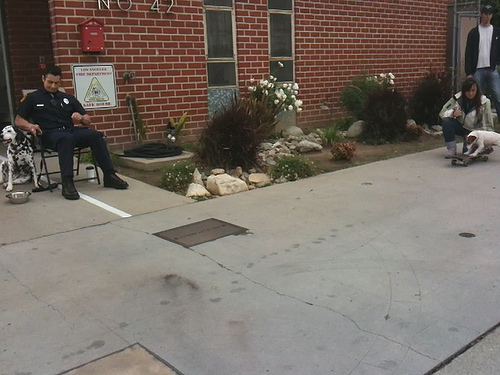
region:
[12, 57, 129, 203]
a man in a uniform sits in a chair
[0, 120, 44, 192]
a dalmation is sitting on the floor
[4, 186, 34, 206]
metal dog water bowl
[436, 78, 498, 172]
a girl with a dog on a skateboard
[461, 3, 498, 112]
a man stands and stares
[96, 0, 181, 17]
no 42 on a red brick wall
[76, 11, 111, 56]
a red mail box on a wall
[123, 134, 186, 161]
a black hose is coiled up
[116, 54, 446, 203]
plants and rocks in a small front yard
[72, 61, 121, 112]
a sign on a red brick wall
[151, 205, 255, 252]
metal grate on the sidewalk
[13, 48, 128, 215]
fireman in a uniform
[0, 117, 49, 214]
white dog with black spots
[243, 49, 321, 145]
white flowers in landscaping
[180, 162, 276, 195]
rocks in the landscaping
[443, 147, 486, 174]
paws on a skateboard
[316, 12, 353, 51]
red bricks on the wall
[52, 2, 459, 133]
building made of brick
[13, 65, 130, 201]
man is sitting in chair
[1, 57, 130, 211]
dalmation dog beside man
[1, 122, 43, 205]
silver bowl in front of dog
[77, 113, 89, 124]
man is wearing a watch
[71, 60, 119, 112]
white sign on building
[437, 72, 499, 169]
woman is petting dog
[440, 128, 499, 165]
dog is trying to skateboard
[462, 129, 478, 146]
brown spot on dog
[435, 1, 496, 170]
man is standing behind woman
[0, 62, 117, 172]
man sitting in chair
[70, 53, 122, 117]
white sign on wall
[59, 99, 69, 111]
silver badge on shirt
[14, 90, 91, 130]
black shirt on man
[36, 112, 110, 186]
black pants on man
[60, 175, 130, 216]
black shoes on feet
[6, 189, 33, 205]
silver dog bowl on ground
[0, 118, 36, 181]
white and black dog sitting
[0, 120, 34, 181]
white and black dalmation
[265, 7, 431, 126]
large red brick wall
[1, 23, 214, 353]
cop by sidewalk with dog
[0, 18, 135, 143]
cop by sidewalk with dog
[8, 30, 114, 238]
cop by sidewalk with dog